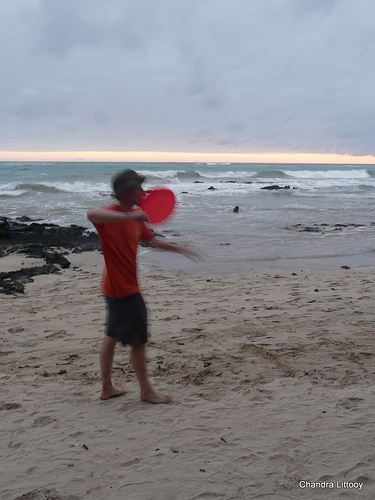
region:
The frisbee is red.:
[133, 185, 186, 226]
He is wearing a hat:
[98, 169, 152, 202]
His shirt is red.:
[84, 209, 159, 303]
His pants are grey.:
[85, 271, 161, 367]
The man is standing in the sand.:
[78, 171, 213, 406]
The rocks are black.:
[5, 208, 78, 275]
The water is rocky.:
[49, 177, 324, 229]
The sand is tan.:
[164, 320, 370, 498]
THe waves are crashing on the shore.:
[30, 170, 343, 230]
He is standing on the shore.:
[16, 136, 372, 464]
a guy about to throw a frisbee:
[88, 159, 201, 412]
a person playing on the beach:
[85, 152, 202, 441]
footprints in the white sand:
[246, 443, 334, 483]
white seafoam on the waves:
[298, 169, 369, 181]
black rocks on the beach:
[9, 218, 79, 265]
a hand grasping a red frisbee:
[135, 203, 154, 222]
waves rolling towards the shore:
[160, 166, 212, 178]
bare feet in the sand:
[83, 378, 206, 416]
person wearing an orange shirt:
[82, 151, 205, 407]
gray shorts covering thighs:
[100, 293, 151, 344]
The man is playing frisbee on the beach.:
[58, 149, 197, 405]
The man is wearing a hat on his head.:
[96, 157, 154, 195]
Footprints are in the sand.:
[157, 407, 322, 498]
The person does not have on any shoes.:
[81, 368, 192, 410]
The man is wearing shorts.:
[98, 287, 168, 359]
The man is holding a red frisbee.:
[77, 176, 213, 242]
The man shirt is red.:
[82, 203, 167, 292]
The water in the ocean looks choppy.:
[184, 162, 330, 209]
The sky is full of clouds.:
[63, 29, 357, 161]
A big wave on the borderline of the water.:
[178, 164, 321, 207]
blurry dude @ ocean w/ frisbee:
[78, 164, 211, 415]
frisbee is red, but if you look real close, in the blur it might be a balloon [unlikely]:
[130, 183, 180, 226]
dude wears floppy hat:
[104, 165, 153, 209]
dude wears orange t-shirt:
[84, 202, 162, 302]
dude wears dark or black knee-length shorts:
[90, 278, 161, 349]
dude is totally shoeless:
[90, 381, 178, 409]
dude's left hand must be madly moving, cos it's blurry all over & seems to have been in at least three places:
[141, 231, 209, 265]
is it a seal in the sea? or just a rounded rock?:
[226, 202, 245, 217]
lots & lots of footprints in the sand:
[0, 267, 374, 498]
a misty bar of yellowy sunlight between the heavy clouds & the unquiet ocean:
[2, 151, 374, 161]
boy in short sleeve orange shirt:
[82, 166, 204, 411]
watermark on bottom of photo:
[295, 474, 364, 492]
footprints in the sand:
[185, 332, 371, 395]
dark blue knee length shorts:
[101, 286, 148, 348]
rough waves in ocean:
[151, 163, 367, 189]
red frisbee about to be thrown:
[138, 185, 178, 227]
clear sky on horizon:
[11, 144, 374, 165]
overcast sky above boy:
[34, 31, 340, 131]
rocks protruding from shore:
[261, 183, 296, 193]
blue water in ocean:
[20, 161, 103, 176]